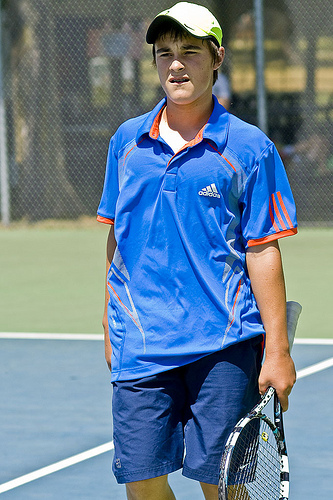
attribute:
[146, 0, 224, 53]
hat — green and white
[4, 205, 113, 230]
leaves — brown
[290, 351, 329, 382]
line — white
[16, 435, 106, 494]
line — white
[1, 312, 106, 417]
tennis court — blue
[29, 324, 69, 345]
line — white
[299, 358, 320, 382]
line — white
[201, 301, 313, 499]
racket — white, striped, blue and white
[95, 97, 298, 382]
shirt — blue and white, blue, short sleeved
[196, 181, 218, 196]
logo — white